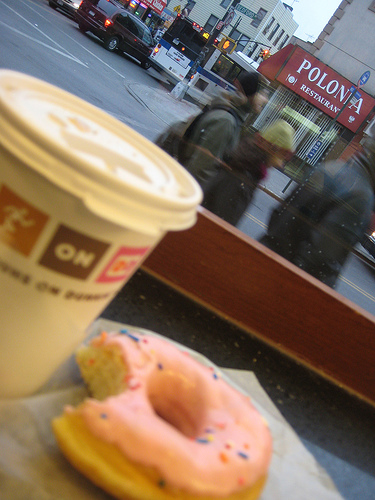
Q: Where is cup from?
A: Dunkin donuts.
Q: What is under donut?
A: Wax paper.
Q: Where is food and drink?
A: On table.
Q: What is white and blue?
A: Bus.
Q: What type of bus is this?
A: Passenger.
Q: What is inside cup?
A: Coffee.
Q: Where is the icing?
A: On donut.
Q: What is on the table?
A: Doughnut.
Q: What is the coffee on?
A: Table.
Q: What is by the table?
A: People walking.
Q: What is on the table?
A: Doughnut.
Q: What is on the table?
A: Coffee and doughnut.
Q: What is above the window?
A: Awning.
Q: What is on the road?
A: Bus.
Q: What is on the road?
A: Bus.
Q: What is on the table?
A: Eaten doughnut.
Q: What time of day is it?
A: Evening.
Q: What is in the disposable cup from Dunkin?
A: Coffee.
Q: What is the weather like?
A: Cold.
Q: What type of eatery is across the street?
A: Restaurant.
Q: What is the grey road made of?
A: Asphalt.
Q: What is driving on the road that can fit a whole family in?
A: Van.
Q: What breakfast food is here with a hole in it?
A: Donut.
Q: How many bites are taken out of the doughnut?
A: 1.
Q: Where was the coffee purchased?
A: Dunkin Doughnuts.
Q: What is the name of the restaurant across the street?
A: Polonia.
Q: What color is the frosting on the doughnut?
A: Pink.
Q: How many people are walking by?
A: 3.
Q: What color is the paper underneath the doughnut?
A: White.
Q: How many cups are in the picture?
A: 1.